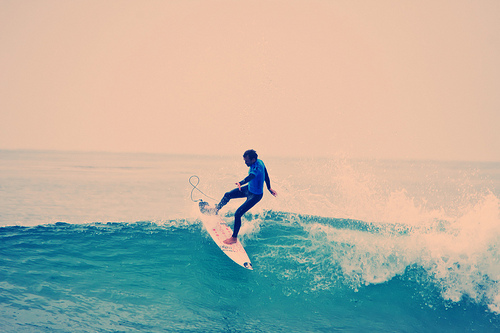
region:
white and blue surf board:
[198, 196, 254, 271]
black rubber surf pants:
[217, 185, 263, 235]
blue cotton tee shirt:
[243, 163, 275, 193]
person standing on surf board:
[190, 145, 277, 272]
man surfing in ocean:
[201, 148, 280, 270]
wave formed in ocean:
[3, 213, 493, 331]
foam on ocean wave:
[319, 197, 499, 300]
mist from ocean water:
[288, 151, 435, 223]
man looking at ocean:
[189, 149, 281, 269]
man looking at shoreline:
[194, 150, 277, 277]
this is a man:
[208, 143, 275, 223]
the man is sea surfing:
[197, 143, 287, 238]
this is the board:
[221, 225, 256, 271]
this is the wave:
[293, 218, 433, 330]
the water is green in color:
[118, 249, 205, 320]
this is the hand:
[235, 173, 256, 185]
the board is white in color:
[231, 243, 243, 257]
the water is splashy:
[367, 185, 437, 214]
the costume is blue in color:
[251, 165, 267, 189]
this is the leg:
[235, 196, 252, 232]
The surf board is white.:
[178, 180, 259, 275]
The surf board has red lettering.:
[176, 178, 250, 272]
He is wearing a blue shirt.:
[230, 160, 272, 195]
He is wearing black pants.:
[208, 179, 266, 235]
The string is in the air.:
[178, 170, 220, 210]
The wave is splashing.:
[256, 160, 496, 316]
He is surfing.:
[3, 141, 489, 330]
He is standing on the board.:
[145, 151, 279, 296]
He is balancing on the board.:
[168, 136, 285, 285]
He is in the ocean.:
[8, 8, 485, 313]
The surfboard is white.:
[198, 203, 251, 266]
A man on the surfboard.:
[187, 139, 282, 271]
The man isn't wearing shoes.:
[192, 189, 242, 254]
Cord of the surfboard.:
[180, 172, 218, 212]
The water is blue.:
[36, 250, 361, 330]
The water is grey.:
[11, 151, 177, 203]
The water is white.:
[305, 195, 485, 285]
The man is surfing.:
[162, 125, 284, 275]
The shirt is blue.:
[240, 160, 270, 200]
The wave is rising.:
[13, 205, 371, 258]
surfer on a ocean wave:
[154, 108, 358, 298]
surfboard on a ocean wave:
[182, 178, 248, 297]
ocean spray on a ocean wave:
[305, 158, 485, 304]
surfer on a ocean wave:
[196, 137, 270, 255]